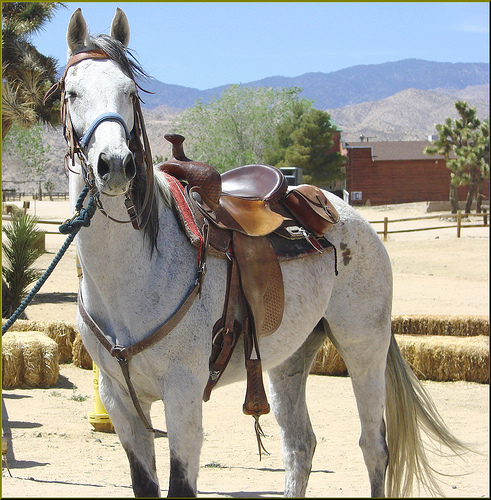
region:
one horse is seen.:
[47, 38, 387, 429]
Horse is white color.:
[75, 69, 384, 411]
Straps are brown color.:
[176, 259, 290, 328]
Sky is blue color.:
[146, 14, 399, 60]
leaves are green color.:
[234, 103, 325, 152]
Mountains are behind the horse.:
[184, 74, 463, 151]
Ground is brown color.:
[414, 244, 475, 299]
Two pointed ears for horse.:
[56, 5, 142, 56]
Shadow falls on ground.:
[4, 396, 277, 499]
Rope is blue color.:
[30, 242, 91, 286]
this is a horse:
[35, 15, 392, 497]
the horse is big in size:
[61, 0, 441, 498]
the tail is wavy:
[391, 361, 428, 482]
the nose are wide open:
[93, 151, 136, 188]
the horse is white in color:
[42, 12, 406, 497]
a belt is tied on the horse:
[93, 287, 196, 366]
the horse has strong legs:
[277, 358, 382, 491]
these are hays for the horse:
[13, 324, 60, 381]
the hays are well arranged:
[5, 324, 52, 379]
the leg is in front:
[277, 370, 321, 497]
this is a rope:
[15, 213, 85, 313]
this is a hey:
[419, 315, 477, 374]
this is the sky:
[167, 4, 373, 34]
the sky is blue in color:
[185, 0, 409, 41]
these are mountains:
[346, 49, 489, 111]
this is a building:
[346, 133, 427, 203]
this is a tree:
[185, 79, 340, 179]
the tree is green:
[176, 69, 340, 179]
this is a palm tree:
[0, 0, 59, 166]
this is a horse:
[79, 200, 416, 476]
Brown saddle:
[167, 129, 296, 269]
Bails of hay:
[416, 303, 488, 388]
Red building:
[344, 126, 470, 208]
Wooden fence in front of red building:
[384, 213, 489, 248]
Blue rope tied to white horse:
[17, 204, 73, 321]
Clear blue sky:
[218, 11, 402, 61]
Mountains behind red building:
[343, 58, 473, 162]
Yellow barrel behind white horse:
[87, 355, 117, 441]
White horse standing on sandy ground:
[59, 13, 175, 496]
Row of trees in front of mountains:
[199, 88, 330, 172]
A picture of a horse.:
[26, 13, 486, 474]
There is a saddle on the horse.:
[147, 126, 347, 290]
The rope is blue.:
[27, 189, 104, 317]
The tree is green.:
[426, 101, 490, 225]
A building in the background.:
[335, 140, 489, 204]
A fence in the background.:
[379, 206, 489, 252]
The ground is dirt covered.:
[400, 245, 487, 310]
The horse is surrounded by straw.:
[398, 309, 490, 390]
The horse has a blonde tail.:
[386, 368, 467, 494]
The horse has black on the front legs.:
[111, 447, 217, 498]